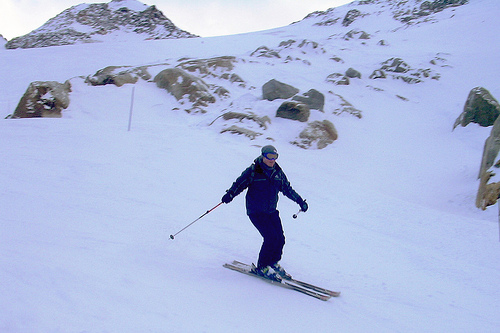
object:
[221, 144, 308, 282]
person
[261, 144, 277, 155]
hat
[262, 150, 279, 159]
goggles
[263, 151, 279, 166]
face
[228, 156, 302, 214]
coat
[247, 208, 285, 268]
pants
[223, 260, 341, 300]
skis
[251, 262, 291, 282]
feet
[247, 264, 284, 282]
boots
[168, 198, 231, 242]
ski poles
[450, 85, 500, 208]
rocks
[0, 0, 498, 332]
ground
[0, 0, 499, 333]
snow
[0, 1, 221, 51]
rocks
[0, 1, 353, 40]
sky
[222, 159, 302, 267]
clothes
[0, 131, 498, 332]
lines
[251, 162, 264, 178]
patch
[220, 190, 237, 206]
gloves